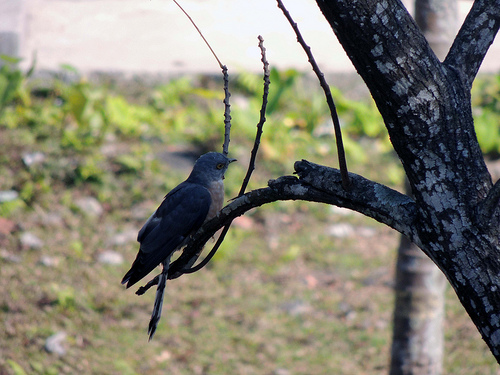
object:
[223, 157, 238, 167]
beak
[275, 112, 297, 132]
yellow leaf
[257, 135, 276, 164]
yellow leaf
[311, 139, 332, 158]
yellow leaf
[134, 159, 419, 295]
branch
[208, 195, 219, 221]
chest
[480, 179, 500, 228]
limb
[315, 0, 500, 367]
trunk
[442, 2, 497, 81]
limb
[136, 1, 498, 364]
tree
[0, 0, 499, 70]
building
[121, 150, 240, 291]
bird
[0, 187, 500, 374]
grass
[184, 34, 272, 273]
branch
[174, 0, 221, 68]
twigs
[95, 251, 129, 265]
rocks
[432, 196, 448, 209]
grey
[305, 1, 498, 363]
tree trunk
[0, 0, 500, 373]
background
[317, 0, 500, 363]
limb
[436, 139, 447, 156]
splotches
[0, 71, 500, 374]
ground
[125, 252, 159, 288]
tail feather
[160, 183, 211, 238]
wing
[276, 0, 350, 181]
branch